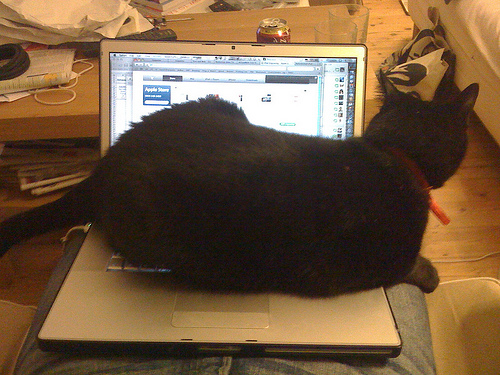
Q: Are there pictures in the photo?
A: No, there are no pictures.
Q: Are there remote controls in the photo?
A: Yes, there is a remote control.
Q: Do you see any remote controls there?
A: Yes, there is a remote control.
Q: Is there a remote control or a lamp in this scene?
A: Yes, there is a remote control.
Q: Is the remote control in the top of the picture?
A: Yes, the remote control is in the top of the image.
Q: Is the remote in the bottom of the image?
A: No, the remote is in the top of the image.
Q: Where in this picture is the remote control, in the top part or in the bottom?
A: The remote control is in the top of the image.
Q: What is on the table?
A: The remote is on the table.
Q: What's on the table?
A: The remote is on the table.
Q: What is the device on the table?
A: The device is a remote control.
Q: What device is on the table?
A: The device is a remote control.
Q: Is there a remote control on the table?
A: Yes, there is a remote control on the table.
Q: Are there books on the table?
A: No, there is a remote control on the table.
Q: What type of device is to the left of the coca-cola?
A: The device is a remote control.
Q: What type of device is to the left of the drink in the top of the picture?
A: The device is a remote control.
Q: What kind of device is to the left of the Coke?
A: The device is a remote control.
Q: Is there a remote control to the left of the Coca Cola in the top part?
A: Yes, there is a remote control to the left of the Coke.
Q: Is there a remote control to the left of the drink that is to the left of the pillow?
A: Yes, there is a remote control to the left of the Coke.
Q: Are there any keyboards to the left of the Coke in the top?
A: No, there is a remote control to the left of the Coca Cola.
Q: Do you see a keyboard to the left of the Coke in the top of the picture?
A: No, there is a remote control to the left of the Coca Cola.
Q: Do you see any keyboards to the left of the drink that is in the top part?
A: No, there is a remote control to the left of the Coca Cola.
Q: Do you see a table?
A: Yes, there is a table.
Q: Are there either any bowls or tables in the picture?
A: Yes, there is a table.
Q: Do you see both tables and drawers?
A: No, there is a table but no drawers.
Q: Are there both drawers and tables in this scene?
A: No, there is a table but no drawers.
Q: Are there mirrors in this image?
A: No, there are no mirrors.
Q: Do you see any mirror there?
A: No, there are no mirrors.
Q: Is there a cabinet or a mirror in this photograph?
A: No, there are no mirrors or cabinets.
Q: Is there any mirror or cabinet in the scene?
A: No, there are no mirrors or cabinets.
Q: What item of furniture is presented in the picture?
A: The piece of furniture is a table.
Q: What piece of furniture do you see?
A: The piece of furniture is a table.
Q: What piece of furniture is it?
A: The piece of furniture is a table.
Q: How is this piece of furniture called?
A: This is a table.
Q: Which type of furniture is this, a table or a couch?
A: This is a table.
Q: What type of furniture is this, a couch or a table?
A: This is a table.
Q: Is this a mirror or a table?
A: This is a table.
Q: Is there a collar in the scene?
A: Yes, there is a collar.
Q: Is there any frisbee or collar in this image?
A: Yes, there is a collar.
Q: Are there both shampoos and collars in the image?
A: No, there is a collar but no shampoos.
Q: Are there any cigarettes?
A: No, there are no cigarettes.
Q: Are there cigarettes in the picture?
A: No, there are no cigarettes.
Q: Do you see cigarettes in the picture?
A: No, there are no cigarettes.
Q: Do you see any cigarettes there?
A: No, there are no cigarettes.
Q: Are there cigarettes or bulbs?
A: No, there are no cigarettes or bulbs.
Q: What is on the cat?
A: The collar is on the cat.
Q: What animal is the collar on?
A: The collar is on the cat.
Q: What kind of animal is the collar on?
A: The collar is on the cat.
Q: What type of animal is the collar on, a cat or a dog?
A: The collar is on a cat.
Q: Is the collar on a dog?
A: No, the collar is on the cat.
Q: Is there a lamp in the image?
A: No, there are no lamps.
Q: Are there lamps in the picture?
A: No, there are no lamps.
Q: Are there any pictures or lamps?
A: No, there are no lamps or pictures.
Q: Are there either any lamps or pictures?
A: No, there are no lamps or pictures.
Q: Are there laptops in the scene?
A: Yes, there is a laptop.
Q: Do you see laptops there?
A: Yes, there is a laptop.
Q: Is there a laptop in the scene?
A: Yes, there is a laptop.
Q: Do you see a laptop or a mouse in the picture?
A: Yes, there is a laptop.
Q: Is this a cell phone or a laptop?
A: This is a laptop.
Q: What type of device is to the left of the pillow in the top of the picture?
A: The device is a laptop.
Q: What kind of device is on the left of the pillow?
A: The device is a laptop.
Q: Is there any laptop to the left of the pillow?
A: Yes, there is a laptop to the left of the pillow.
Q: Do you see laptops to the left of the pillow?
A: Yes, there is a laptop to the left of the pillow.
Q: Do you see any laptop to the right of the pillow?
A: No, the laptop is to the left of the pillow.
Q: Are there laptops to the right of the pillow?
A: No, the laptop is to the left of the pillow.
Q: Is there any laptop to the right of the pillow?
A: No, the laptop is to the left of the pillow.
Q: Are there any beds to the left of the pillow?
A: No, there is a laptop to the left of the pillow.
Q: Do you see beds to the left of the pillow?
A: No, there is a laptop to the left of the pillow.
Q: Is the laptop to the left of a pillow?
A: Yes, the laptop is to the left of a pillow.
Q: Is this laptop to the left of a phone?
A: No, the laptop is to the left of a pillow.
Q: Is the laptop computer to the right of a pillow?
A: No, the laptop computer is to the left of a pillow.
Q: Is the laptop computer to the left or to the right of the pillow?
A: The laptop computer is to the left of the pillow.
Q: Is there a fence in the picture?
A: No, there are no fences.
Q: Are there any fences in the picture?
A: No, there are no fences.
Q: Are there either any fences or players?
A: No, there are no fences or players.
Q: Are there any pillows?
A: Yes, there is a pillow.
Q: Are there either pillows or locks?
A: Yes, there is a pillow.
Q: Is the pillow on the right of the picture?
A: Yes, the pillow is on the right of the image.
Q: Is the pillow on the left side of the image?
A: No, the pillow is on the right of the image.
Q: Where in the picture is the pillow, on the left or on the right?
A: The pillow is on the right of the image.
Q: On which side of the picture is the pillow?
A: The pillow is on the right of the image.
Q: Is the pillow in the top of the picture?
A: Yes, the pillow is in the top of the image.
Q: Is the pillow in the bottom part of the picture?
A: No, the pillow is in the top of the image.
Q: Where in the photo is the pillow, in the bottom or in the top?
A: The pillow is in the top of the image.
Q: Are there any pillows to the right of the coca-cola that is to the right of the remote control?
A: Yes, there is a pillow to the right of the Coke.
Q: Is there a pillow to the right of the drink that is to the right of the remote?
A: Yes, there is a pillow to the right of the Coke.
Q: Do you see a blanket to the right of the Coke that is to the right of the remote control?
A: No, there is a pillow to the right of the Coke.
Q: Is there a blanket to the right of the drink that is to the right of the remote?
A: No, there is a pillow to the right of the Coke.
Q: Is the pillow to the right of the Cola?
A: Yes, the pillow is to the right of the Cola.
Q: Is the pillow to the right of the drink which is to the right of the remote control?
A: Yes, the pillow is to the right of the Cola.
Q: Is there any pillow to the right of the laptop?
A: Yes, there is a pillow to the right of the laptop.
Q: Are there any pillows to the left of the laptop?
A: No, the pillow is to the right of the laptop.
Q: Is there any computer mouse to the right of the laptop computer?
A: No, there is a pillow to the right of the laptop computer.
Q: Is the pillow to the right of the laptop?
A: Yes, the pillow is to the right of the laptop.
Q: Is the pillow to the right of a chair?
A: No, the pillow is to the right of the laptop.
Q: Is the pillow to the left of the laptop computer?
A: No, the pillow is to the right of the laptop computer.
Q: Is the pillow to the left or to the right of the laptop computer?
A: The pillow is to the right of the laptop computer.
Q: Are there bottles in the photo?
A: No, there are no bottles.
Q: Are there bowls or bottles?
A: No, there are no bottles or bowls.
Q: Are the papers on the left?
A: Yes, the papers are on the left of the image.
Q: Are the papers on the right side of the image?
A: No, the papers are on the left of the image.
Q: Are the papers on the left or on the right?
A: The papers are on the left of the image.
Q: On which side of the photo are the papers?
A: The papers are on the left of the image.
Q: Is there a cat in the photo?
A: Yes, there is a cat.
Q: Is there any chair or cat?
A: Yes, there is a cat.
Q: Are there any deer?
A: No, there are no deer.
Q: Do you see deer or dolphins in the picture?
A: No, there are no deer or dolphins.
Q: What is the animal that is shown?
A: The animal is a cat.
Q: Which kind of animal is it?
A: The animal is a cat.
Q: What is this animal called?
A: This is a cat.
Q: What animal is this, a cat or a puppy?
A: This is a cat.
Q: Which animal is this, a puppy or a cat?
A: This is a cat.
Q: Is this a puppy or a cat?
A: This is a cat.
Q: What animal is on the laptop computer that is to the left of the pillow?
A: The cat is on the laptop.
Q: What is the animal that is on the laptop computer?
A: The animal is a cat.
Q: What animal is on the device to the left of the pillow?
A: The animal is a cat.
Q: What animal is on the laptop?
A: The animal is a cat.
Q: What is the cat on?
A: The cat is on the laptop.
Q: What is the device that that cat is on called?
A: The device is a laptop.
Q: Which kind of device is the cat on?
A: The cat is on the laptop computer.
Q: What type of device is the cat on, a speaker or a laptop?
A: The cat is on a laptop.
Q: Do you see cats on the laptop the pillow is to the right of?
A: Yes, there is a cat on the laptop computer.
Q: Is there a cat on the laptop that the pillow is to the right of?
A: Yes, there is a cat on the laptop computer.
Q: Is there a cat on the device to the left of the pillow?
A: Yes, there is a cat on the laptop computer.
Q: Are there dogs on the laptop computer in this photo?
A: No, there is a cat on the laptop computer.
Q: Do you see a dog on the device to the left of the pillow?
A: No, there is a cat on the laptop computer.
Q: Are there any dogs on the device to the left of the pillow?
A: No, there is a cat on the laptop computer.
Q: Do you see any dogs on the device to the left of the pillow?
A: No, there is a cat on the laptop computer.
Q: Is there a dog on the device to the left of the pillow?
A: No, there is a cat on the laptop computer.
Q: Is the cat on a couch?
A: No, the cat is on a laptop.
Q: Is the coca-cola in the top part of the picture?
A: Yes, the coca-cola is in the top of the image.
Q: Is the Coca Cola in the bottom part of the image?
A: No, the Coca Cola is in the top of the image.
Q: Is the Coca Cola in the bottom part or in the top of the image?
A: The Coca Cola is in the top of the image.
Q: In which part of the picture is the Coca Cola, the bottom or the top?
A: The Coca Cola is in the top of the image.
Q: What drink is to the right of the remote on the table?
A: The drink is Coke.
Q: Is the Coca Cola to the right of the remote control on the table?
A: Yes, the Coca Cola is to the right of the remote.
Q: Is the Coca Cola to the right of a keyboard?
A: No, the Coca Cola is to the right of the remote.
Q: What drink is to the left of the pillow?
A: The drink is Coke.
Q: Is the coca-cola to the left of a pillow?
A: Yes, the coca-cola is to the left of a pillow.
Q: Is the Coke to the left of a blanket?
A: No, the Coke is to the left of a pillow.